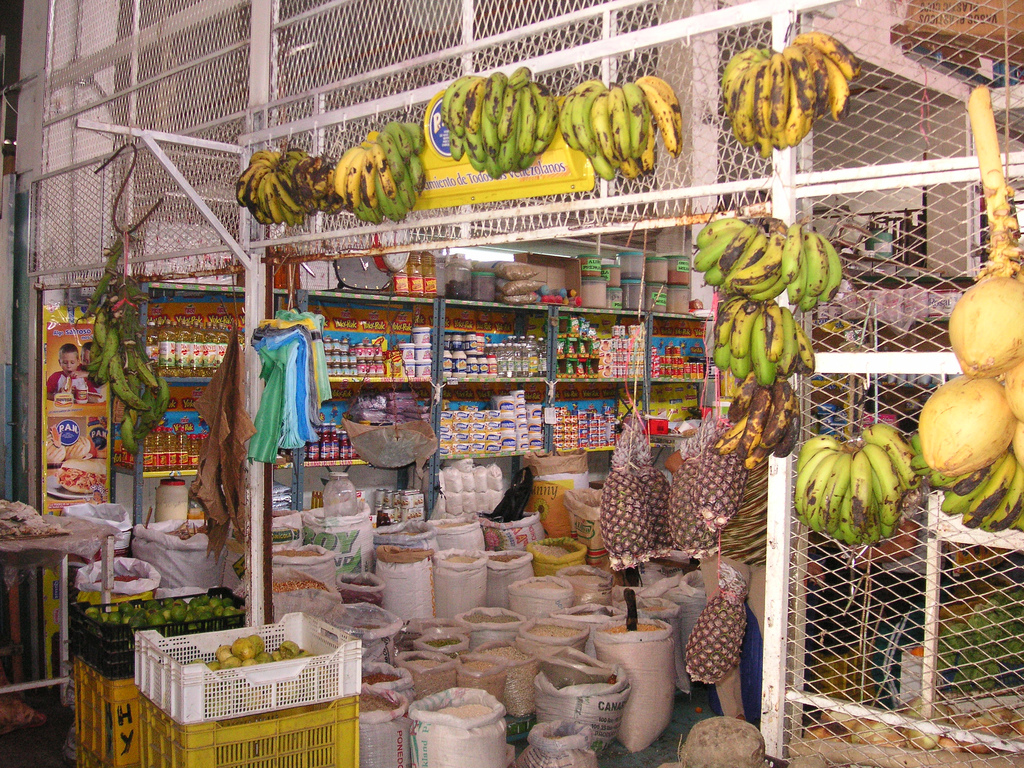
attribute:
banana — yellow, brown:
[798, 33, 862, 84]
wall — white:
[27, 7, 1016, 767]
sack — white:
[408, 685, 503, 766]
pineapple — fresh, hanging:
[599, 412, 664, 577]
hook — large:
[92, 146, 164, 237]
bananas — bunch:
[332, 124, 428, 223]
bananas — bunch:
[427, 67, 562, 177]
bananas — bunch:
[563, 78, 688, 182]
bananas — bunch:
[698, 211, 842, 311]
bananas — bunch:
[799, 429, 913, 551]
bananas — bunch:
[910, 442, 1021, 537]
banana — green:
[822, 236, 844, 313]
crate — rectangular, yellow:
[141, 702, 360, 764]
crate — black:
[72, 586, 255, 678]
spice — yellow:
[608, 621, 662, 635]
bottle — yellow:
[152, 423, 168, 474]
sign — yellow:
[412, 85, 598, 219]